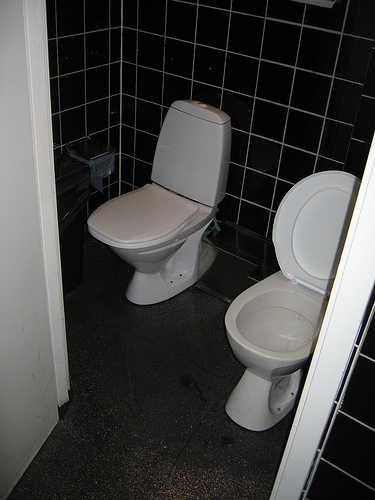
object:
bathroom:
[0, 1, 375, 500]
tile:
[221, 51, 258, 97]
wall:
[118, 0, 375, 242]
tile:
[239, 167, 277, 210]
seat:
[223, 271, 325, 384]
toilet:
[223, 169, 360, 430]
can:
[55, 155, 89, 298]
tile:
[244, 135, 283, 179]